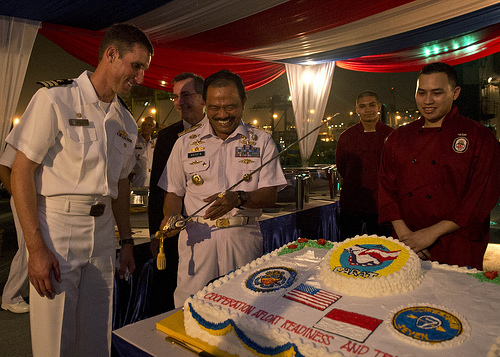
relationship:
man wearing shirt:
[6, 23, 153, 353] [6, 65, 143, 207]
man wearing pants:
[6, 23, 153, 353] [13, 188, 128, 350]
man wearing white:
[157, 69, 288, 309] [157, 119, 287, 309]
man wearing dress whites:
[6, 23, 153, 353] [4, 70, 138, 356]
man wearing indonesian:
[150, 67, 292, 312] [156, 119, 286, 309]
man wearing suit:
[146, 73, 205, 320] [147, 119, 194, 240]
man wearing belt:
[152, 68, 278, 268] [180, 212, 262, 231]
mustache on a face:
[212, 113, 238, 125] [198, 70, 246, 138]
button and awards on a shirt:
[83, 104, 159, 184] [154, 120, 289, 218]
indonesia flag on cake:
[229, 289, 324, 357] [235, 238, 489, 357]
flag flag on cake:
[282, 283, 342, 311] [154, 243, 471, 357]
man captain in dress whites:
[5, 23, 138, 356] [13, 75, 138, 355]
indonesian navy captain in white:
[169, 106, 269, 334] [190, 189, 250, 315]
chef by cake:
[387, 70, 492, 238] [172, 208, 492, 348]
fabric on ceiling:
[0, 0, 498, 65] [214, 50, 270, 91]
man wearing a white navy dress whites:
[5, 23, 138, 356] [4, 70, 138, 356]